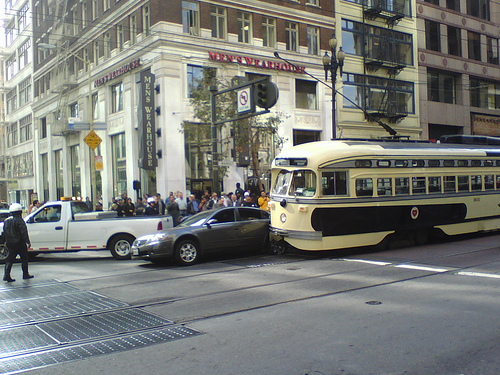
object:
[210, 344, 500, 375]
sidewalks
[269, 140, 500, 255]
trolley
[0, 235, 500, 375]
street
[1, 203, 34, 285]
officer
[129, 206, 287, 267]
car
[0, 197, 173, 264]
truck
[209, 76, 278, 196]
pole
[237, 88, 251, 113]
sign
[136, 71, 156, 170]
sign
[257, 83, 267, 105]
lights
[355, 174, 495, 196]
windows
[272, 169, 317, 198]
windows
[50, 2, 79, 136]
fire escape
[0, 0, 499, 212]
building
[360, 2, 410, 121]
fire escape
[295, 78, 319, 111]
window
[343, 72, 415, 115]
window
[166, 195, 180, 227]
person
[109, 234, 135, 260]
tire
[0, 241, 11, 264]
tire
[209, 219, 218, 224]
mirror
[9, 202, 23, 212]
helmet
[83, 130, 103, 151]
sign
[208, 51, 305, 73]
sign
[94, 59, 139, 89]
sign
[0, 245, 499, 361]
tracks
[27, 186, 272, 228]
pedestrians